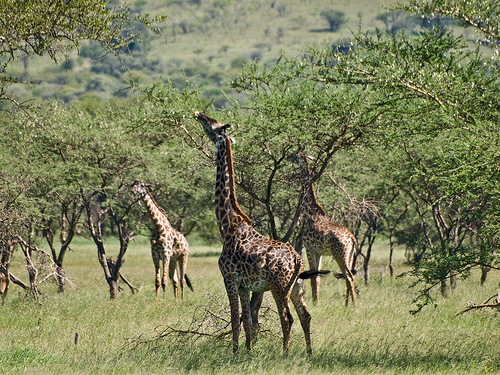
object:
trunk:
[0, 237, 14, 294]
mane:
[226, 135, 251, 225]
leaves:
[0, 0, 168, 60]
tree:
[0, 2, 172, 301]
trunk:
[104, 278, 117, 298]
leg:
[216, 258, 241, 353]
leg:
[238, 284, 253, 354]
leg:
[267, 272, 295, 355]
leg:
[289, 276, 312, 352]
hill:
[0, 0, 500, 92]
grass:
[0, 262, 500, 374]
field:
[0, 235, 499, 373]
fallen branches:
[119, 299, 284, 352]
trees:
[346, 0, 500, 294]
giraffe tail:
[293, 254, 332, 281]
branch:
[116, 290, 278, 351]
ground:
[344, 310, 496, 358]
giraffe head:
[193, 110, 232, 139]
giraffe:
[283, 151, 359, 307]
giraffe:
[130, 179, 195, 302]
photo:
[0, 0, 500, 374]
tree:
[96, 35, 498, 301]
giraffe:
[191, 109, 312, 359]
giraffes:
[127, 112, 359, 360]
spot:
[230, 226, 250, 242]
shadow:
[178, 341, 481, 368]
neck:
[209, 141, 249, 240]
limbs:
[306, 125, 358, 174]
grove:
[0, 0, 500, 240]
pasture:
[0, 220, 500, 374]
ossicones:
[220, 123, 234, 132]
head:
[192, 111, 230, 143]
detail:
[74, 78, 434, 217]